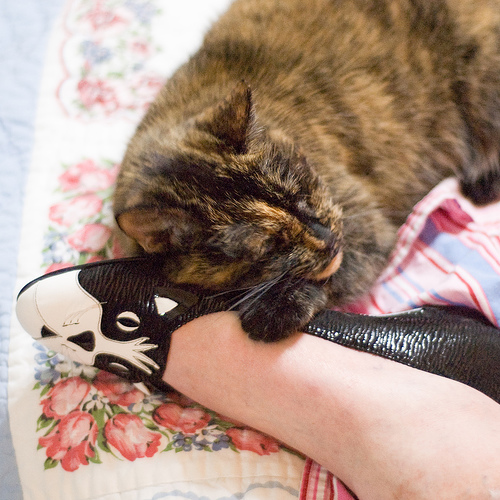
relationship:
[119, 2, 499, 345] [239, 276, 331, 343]
cat has paw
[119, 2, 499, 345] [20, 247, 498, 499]
cat resting on foot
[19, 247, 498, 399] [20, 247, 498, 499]
shoe on foot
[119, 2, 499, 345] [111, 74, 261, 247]
cat has ears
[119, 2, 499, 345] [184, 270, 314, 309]
cat has whiskers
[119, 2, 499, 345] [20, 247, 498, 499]
cat sleeping on foot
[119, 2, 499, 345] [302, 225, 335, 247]
cat has nose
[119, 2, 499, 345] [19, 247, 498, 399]
cat sleeping on shoe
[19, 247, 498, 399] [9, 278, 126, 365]
shoe has tip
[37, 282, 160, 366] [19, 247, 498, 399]
face on shoe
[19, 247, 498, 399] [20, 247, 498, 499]
shoe on womans foot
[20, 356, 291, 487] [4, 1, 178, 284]
roses on sheet